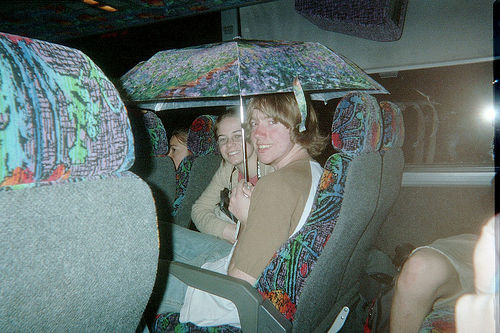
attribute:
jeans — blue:
[127, 236, 237, 308]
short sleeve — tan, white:
[179, 157, 324, 327]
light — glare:
[466, 97, 498, 129]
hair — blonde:
[248, 83, 332, 137]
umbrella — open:
[117, 32, 398, 196]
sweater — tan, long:
[191, 163, 267, 218]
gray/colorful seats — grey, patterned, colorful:
[253, 84, 420, 329]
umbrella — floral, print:
[119, 36, 397, 117]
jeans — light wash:
[140, 223, 232, 324]